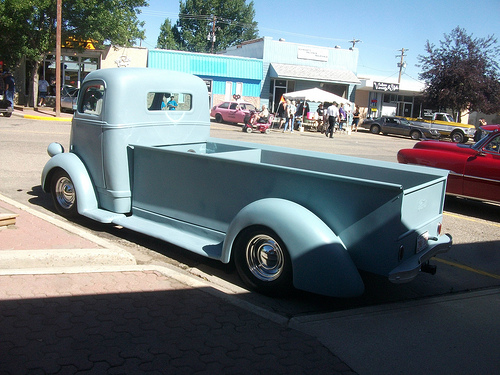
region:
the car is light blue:
[36, 45, 461, 305]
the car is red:
[392, 100, 495, 216]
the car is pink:
[215, 82, 276, 137]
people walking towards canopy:
[257, 78, 367, 153]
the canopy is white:
[273, 75, 364, 112]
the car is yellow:
[417, 101, 468, 134]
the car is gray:
[366, 112, 436, 157]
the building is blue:
[146, 35, 256, 101]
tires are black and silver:
[40, 173, 310, 298]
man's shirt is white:
[320, 99, 341, 120]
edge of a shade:
[66, 287, 81, 296]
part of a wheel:
[223, 210, 291, 295]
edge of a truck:
[378, 172, 399, 252]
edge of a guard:
[293, 270, 310, 291]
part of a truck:
[281, 152, 336, 242]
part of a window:
[83, 87, 110, 117]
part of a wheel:
[273, 250, 284, 262]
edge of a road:
[138, 248, 149, 264]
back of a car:
[336, 201, 338, 210]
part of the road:
[431, 292, 435, 296]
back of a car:
[387, 227, 406, 241]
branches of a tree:
[261, 286, 271, 306]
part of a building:
[298, 50, 325, 78]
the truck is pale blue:
[57, 51, 403, 298]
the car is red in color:
[406, 112, 496, 210]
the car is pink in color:
[216, 96, 268, 135]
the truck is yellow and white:
[401, 101, 479, 144]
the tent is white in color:
[278, 75, 369, 123]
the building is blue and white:
[143, 41, 286, 131]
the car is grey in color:
[362, 101, 444, 149]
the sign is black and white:
[368, 77, 406, 96]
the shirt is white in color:
[323, 102, 349, 119]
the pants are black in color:
[321, 112, 344, 138]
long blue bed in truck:
[132, 124, 460, 295]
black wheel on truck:
[232, 217, 308, 310]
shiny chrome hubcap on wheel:
[239, 231, 291, 281]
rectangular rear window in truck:
[130, 81, 200, 113]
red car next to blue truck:
[403, 135, 498, 217]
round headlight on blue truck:
[45, 140, 66, 153]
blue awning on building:
[137, 34, 263, 131]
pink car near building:
[193, 88, 263, 131]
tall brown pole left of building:
[48, 3, 73, 113]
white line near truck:
[46, 204, 277, 346]